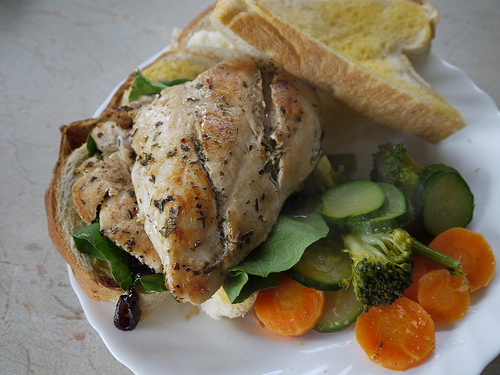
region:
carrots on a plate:
[340, 290, 414, 355]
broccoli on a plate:
[335, 238, 417, 295]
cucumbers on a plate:
[341, 177, 418, 232]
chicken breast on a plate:
[109, 112, 277, 249]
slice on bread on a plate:
[261, 20, 446, 150]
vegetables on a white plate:
[231, 223, 422, 373]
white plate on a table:
[37, 226, 193, 371]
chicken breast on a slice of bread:
[18, 84, 258, 270]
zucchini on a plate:
[338, 131, 456, 247]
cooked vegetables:
[276, 204, 490, 360]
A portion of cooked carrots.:
[271, 234, 481, 357]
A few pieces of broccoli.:
[310, 132, 421, 306]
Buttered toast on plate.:
[229, 0, 456, 124]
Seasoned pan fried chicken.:
[89, 68, 319, 283]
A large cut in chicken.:
[233, 65, 291, 202]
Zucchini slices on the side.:
[292, 161, 479, 340]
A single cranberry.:
[105, 288, 145, 333]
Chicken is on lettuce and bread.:
[50, 58, 325, 290]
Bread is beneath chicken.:
[37, 119, 299, 301]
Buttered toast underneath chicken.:
[49, 31, 319, 304]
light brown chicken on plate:
[72, 102, 287, 284]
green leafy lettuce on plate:
[238, 170, 400, 282]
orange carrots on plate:
[265, 224, 486, 351]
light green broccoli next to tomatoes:
[348, 222, 400, 303]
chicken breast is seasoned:
[70, 84, 325, 303]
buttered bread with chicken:
[136, 2, 476, 74]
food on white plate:
[141, 25, 493, 340]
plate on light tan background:
[3, 7, 499, 374]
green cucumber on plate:
[290, 179, 467, 254]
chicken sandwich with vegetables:
[27, 3, 427, 289]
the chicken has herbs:
[79, 55, 326, 305]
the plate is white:
[68, 24, 497, 373]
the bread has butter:
[216, 0, 463, 142]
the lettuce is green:
[226, 200, 323, 300]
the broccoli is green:
[338, 145, 460, 308]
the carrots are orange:
[256, 228, 494, 370]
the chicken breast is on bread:
[81, 61, 321, 315]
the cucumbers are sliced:
[331, 168, 476, 240]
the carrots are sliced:
[258, 226, 495, 368]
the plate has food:
[47, 5, 498, 372]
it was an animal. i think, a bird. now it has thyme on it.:
[63, 63, 323, 308]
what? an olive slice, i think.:
[106, 292, 148, 336]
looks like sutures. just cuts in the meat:
[186, 66, 286, 251]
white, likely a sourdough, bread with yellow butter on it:
[202, 4, 473, 149]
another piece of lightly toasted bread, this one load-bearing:
[36, 47, 266, 330]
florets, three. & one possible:
[291, 139, 462, 317]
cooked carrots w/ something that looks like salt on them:
[248, 254, 493, 369]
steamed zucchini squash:
[293, 162, 481, 337]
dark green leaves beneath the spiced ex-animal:
[68, 65, 328, 310]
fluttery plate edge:
[401, 40, 498, 190]